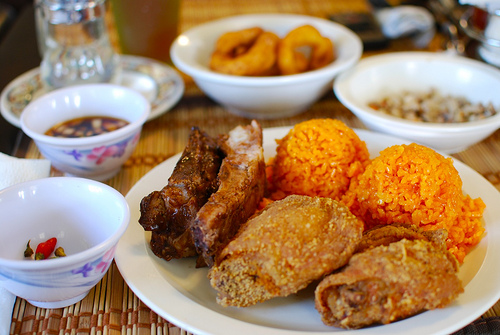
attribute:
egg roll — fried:
[312, 228, 465, 333]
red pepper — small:
[36, 235, 57, 257]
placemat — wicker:
[8, 279, 172, 334]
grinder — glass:
[34, 0, 124, 92]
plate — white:
[192, 130, 486, 315]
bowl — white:
[334, 47, 499, 153]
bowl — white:
[170, 10, 362, 118]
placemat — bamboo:
[5, 80, 495, 334]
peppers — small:
[4, 209, 90, 271]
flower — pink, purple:
[67, 260, 98, 282]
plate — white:
[114, 120, 499, 334]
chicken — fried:
[221, 176, 459, 320]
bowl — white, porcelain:
[1, 175, 131, 309]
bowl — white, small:
[19, 83, 150, 180]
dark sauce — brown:
[43, 108, 130, 137]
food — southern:
[148, 115, 477, 325]